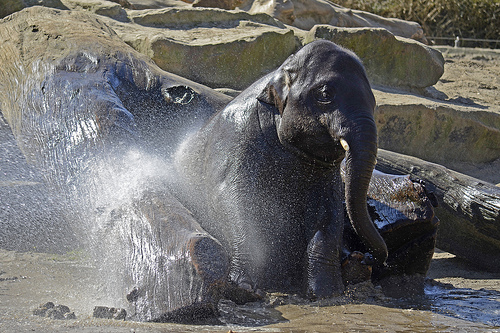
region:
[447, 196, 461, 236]
THE TREE TRUNK IS BLACK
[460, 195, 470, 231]
THE TREE TRUNK IS BLACK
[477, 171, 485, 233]
THE TREE TRUNK IS BLACK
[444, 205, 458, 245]
THE TREE TRUNK IS BLACK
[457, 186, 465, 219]
THE TREE TRUNK IS BLACK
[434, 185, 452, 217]
THE TREE TRUNK IS BLACK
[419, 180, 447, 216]
THE TREE TRUNK IS BLACK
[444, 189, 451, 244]
THE TREE TRUNK IS BLACK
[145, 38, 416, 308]
elephant sitting down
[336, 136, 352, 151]
small white tusk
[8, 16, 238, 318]
thick tree trunk propped up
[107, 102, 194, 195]
speckles of water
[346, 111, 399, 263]
long, thick, gray trunk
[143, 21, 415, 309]
elephant sitting in the water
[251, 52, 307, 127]
wet ear that is folded in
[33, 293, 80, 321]
pile of rocks on the sand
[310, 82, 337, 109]
small, round, black eye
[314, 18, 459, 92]
large tan boulder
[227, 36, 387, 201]
A young elephant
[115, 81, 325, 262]
A elephant being sprayed with water.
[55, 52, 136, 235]
A cut tree trunk.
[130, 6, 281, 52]
A slab of rock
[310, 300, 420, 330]
The ground is wet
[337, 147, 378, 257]
the elephants trunk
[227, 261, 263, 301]
a elephants round foot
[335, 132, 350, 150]
A small white tusk.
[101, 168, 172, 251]
The wood is wet.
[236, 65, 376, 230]
the elephant is wet.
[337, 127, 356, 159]
white tusk on elephant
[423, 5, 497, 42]
bushes with green leaves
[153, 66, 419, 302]
gray elephant sitting down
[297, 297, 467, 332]
standing water on ground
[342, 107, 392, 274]
gray elephant trunk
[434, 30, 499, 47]
white metal guard wire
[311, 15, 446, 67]
large gray boulder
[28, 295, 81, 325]
elephant droppings on ground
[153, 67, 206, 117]
knot on side of tree trunk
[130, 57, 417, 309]
elephant being sprayed with water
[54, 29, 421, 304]
the elephant is in water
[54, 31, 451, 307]
the elephant is between a log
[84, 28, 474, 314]
the elephant has tusks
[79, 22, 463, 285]
this is an asian elephant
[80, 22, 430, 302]
the elephant is wet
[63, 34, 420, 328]
there is a lot of water spray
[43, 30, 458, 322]
this elephant is in captivity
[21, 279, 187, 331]
piles of poop in the cage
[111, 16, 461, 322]
elephants like to bathe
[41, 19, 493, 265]
the elephant is sitting down